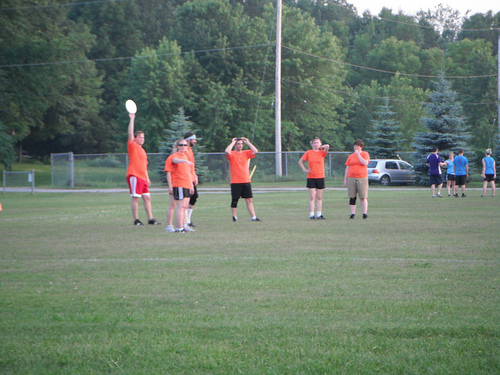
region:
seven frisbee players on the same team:
[119, 97, 372, 232]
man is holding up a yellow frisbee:
[123, 89, 161, 229]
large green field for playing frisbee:
[5, 184, 495, 374]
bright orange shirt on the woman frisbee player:
[302, 143, 329, 183]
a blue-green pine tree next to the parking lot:
[410, 61, 471, 183]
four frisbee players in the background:
[423, 147, 499, 196]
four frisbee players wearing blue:
[428, 146, 499, 197]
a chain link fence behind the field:
[54, 147, 361, 191]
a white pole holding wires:
[268, 1, 288, 178]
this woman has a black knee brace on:
[349, 194, 357, 205]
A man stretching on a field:
[124, 98, 159, 223]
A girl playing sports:
[298, 137, 329, 219]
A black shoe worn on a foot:
[347, 214, 355, 219]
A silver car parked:
[365, 160, 425, 185]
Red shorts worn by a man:
[126, 173, 151, 197]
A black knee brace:
[349, 196, 355, 203]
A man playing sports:
[224, 136, 259, 221]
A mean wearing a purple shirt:
[424, 148, 444, 196]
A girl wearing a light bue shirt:
[480, 147, 497, 195]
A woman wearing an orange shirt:
[297, 137, 329, 219]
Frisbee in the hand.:
[123, 96, 140, 116]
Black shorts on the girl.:
[295, 133, 330, 221]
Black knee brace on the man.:
[221, 133, 267, 223]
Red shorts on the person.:
[124, 111, 156, 224]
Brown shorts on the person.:
[342, 136, 369, 220]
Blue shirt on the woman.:
[480, 146, 499, 196]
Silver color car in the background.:
[362, 150, 427, 186]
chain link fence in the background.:
[48, 145, 351, 190]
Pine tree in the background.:
[407, 68, 476, 186]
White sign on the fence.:
[25, 170, 37, 184]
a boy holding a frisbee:
[117, 87, 162, 224]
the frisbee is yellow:
[122, 95, 139, 115]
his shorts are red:
[122, 172, 156, 200]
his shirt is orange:
[125, 140, 152, 175]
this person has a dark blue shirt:
[425, 147, 445, 197]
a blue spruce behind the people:
[412, 67, 482, 183]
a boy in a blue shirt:
[447, 149, 469, 179]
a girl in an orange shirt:
[302, 144, 327, 181]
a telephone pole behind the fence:
[272, 0, 289, 182]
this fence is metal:
[47, 144, 377, 187]